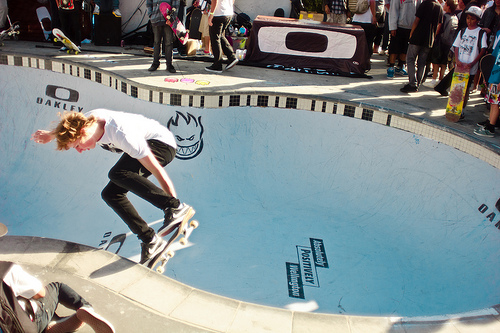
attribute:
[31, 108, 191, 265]
man — skateboarder, skateboarding, young, doing a trick, bent forward, skater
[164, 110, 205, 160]
fireball — smiling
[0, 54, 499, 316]
pool — empty, for skateboarding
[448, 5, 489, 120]
boy — young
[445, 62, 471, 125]
skateboard — yellow, red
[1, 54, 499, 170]
edge — gray, black, white, striped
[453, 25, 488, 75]
t shirt — white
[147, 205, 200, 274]
skateboard — black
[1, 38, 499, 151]
pavement — gray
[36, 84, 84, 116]
logo — for oakley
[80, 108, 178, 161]
shirt — white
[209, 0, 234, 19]
shirt — white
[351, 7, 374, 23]
shirt — white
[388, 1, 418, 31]
shirt — gray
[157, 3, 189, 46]
skateboard — pink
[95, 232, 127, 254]
logo — for oakley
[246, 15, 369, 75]
tablecloth — white, black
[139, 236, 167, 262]
shoe — black, nike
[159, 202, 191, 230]
shoe — black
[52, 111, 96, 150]
hair — long